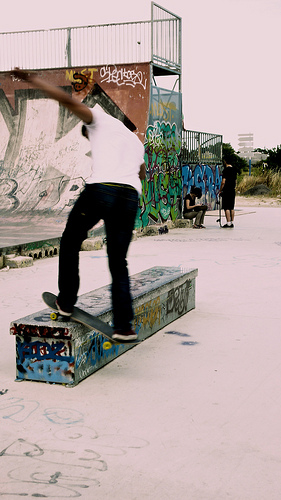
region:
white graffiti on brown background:
[89, 66, 147, 94]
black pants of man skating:
[57, 178, 136, 324]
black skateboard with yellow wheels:
[40, 288, 137, 353]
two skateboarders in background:
[180, 155, 237, 230]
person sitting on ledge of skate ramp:
[180, 185, 208, 229]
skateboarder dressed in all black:
[212, 154, 239, 231]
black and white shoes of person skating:
[52, 291, 135, 342]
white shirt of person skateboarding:
[84, 106, 140, 191]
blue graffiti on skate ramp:
[181, 162, 219, 204]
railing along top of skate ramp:
[6, 14, 180, 69]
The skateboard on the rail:
[39, 290, 142, 350]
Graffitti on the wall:
[14, 329, 73, 385]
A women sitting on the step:
[179, 184, 208, 230]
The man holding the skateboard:
[214, 151, 239, 228]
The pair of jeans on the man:
[60, 178, 136, 320]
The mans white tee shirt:
[84, 105, 143, 194]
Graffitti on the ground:
[0, 396, 138, 498]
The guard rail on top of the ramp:
[8, 0, 181, 68]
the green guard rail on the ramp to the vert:
[182, 130, 223, 162]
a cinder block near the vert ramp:
[2, 251, 33, 270]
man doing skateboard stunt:
[10, 64, 197, 390]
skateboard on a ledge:
[38, 292, 138, 348]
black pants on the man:
[56, 183, 137, 329]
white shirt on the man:
[83, 108, 142, 195]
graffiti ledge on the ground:
[14, 264, 199, 382]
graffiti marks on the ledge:
[17, 355, 74, 383]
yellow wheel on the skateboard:
[100, 339, 114, 351]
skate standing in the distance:
[215, 158, 240, 230]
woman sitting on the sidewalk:
[182, 187, 203, 227]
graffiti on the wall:
[0, 174, 86, 217]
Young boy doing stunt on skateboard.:
[4, 65, 148, 346]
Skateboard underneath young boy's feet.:
[41, 291, 142, 354]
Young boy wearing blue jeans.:
[54, 181, 141, 330]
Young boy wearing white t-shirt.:
[80, 102, 150, 199]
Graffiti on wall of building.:
[143, 122, 181, 223]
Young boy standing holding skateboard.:
[215, 154, 238, 231]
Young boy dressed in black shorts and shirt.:
[218, 154, 242, 211]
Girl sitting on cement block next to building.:
[178, 185, 210, 229]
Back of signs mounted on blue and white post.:
[235, 130, 257, 175]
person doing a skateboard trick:
[11, 65, 142, 340]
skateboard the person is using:
[39, 287, 143, 350]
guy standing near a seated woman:
[220, 152, 237, 228]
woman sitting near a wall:
[185, 186, 207, 232]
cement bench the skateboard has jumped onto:
[8, 263, 202, 388]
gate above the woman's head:
[182, 126, 224, 165]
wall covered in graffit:
[120, 118, 187, 228]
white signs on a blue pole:
[237, 131, 253, 175]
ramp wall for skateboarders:
[2, 66, 140, 261]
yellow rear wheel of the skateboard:
[100, 340, 112, 351]